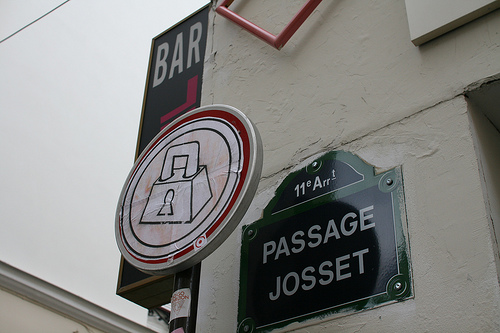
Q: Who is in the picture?
A: No one.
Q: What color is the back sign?
A: Black, red, white.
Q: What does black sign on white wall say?
A: PASSAGE JOSSET.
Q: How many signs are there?
A: 3.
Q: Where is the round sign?
A: Pole.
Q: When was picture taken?
A: Daytime.